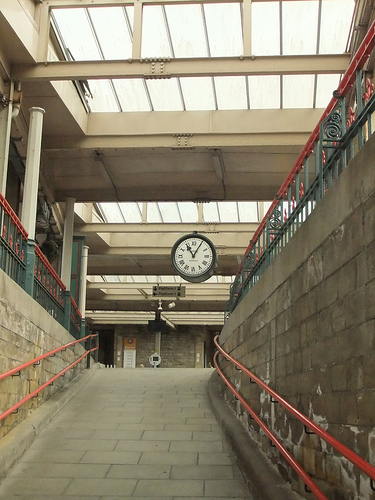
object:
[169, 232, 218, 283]
clock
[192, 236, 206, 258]
arrows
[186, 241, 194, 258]
arrows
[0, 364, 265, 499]
ramp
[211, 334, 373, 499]
rails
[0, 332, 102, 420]
rails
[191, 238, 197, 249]
number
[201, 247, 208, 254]
number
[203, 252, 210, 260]
number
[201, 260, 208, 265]
number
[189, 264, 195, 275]
number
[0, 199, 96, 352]
fence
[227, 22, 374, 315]
fence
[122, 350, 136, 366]
sign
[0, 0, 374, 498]
station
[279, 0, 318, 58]
windows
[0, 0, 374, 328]
ceiling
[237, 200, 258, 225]
windows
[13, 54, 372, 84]
beams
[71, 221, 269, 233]
beams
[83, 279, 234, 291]
beams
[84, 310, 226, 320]
beams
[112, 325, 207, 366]
wall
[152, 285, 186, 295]
sign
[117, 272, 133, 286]
windows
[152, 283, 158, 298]
directions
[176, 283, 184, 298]
directions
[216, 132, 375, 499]
wall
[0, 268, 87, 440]
wall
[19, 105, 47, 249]
column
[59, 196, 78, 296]
column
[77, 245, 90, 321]
column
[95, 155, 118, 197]
light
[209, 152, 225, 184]
light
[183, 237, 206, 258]
time